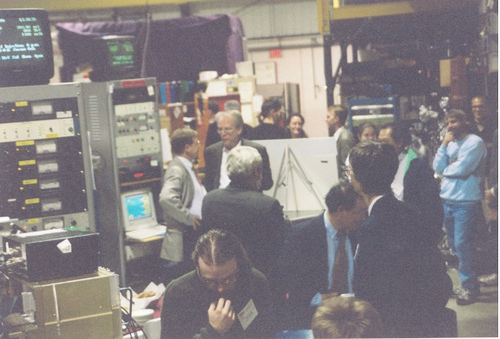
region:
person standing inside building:
[343, 136, 457, 331]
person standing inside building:
[436, 108, 487, 305]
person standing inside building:
[277, 181, 364, 318]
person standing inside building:
[201, 142, 287, 272]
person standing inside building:
[156, 130, 208, 270]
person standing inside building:
[200, 111, 271, 201]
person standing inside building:
[247, 100, 284, 139]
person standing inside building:
[282, 110, 308, 140]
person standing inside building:
[325, 103, 354, 168]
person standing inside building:
[466, 94, 491, 138]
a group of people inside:
[121, 72, 431, 336]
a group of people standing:
[157, 68, 454, 311]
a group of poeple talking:
[215, 91, 494, 280]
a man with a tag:
[153, 205, 278, 337]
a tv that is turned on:
[4, 5, 82, 87]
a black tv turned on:
[7, 3, 99, 110]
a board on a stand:
[201, 91, 474, 259]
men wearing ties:
[167, 101, 469, 333]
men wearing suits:
[144, 101, 494, 329]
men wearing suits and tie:
[154, 64, 493, 311]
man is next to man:
[346, 143, 458, 335]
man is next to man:
[273, 183, 370, 331]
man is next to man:
[199, 146, 297, 327]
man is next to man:
[163, 228, 275, 336]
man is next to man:
[160, 130, 204, 282]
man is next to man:
[202, 110, 272, 192]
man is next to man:
[430, 106, 490, 304]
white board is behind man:
[239, 138, 336, 222]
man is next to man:
[323, 103, 354, 183]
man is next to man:
[258, 99, 289, 136]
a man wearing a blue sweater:
[435, 108, 487, 305]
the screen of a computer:
[119, 192, 156, 227]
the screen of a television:
[3, 7, 53, 84]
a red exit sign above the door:
[268, 48, 283, 58]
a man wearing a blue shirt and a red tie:
[291, 190, 366, 292]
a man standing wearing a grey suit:
[161, 130, 205, 253]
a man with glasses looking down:
[165, 225, 277, 332]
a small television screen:
[92, 31, 139, 79]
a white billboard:
[252, 135, 341, 210]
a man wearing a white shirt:
[325, 105, 349, 136]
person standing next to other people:
[148, 120, 208, 267]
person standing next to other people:
[150, 222, 279, 337]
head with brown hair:
[305, 290, 388, 337]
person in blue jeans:
[429, 101, 489, 306]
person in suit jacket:
[322, 96, 357, 171]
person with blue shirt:
[270, 178, 369, 325]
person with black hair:
[240, 94, 300, 139]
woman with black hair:
[280, 104, 314, 139]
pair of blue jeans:
[444, 192, 486, 290]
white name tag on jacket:
[234, 297, 262, 329]